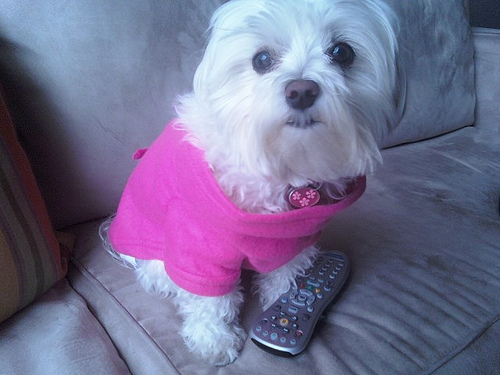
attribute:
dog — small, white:
[98, 0, 401, 367]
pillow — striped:
[4, 62, 70, 315]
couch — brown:
[1, 0, 498, 367]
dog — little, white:
[127, 9, 405, 324]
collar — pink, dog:
[280, 176, 330, 208]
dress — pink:
[104, 110, 365, 312]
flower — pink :
[289, 189, 300, 201]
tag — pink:
[287, 186, 319, 208]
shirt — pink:
[111, 118, 367, 294]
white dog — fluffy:
[99, 1, 403, 367]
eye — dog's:
[250, 47, 277, 77]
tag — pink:
[278, 177, 316, 204]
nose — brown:
[282, 75, 322, 110]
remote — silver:
[241, 220, 369, 372]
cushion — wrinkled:
[56, 125, 498, 374]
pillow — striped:
[2, 96, 69, 328]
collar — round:
[289, 185, 321, 212]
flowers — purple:
[291, 190, 314, 209]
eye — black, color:
[246, 45, 276, 78]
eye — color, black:
[323, 34, 357, 76]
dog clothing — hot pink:
[87, 122, 372, 309]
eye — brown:
[330, 42, 355, 67]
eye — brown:
[252, 49, 272, 71]